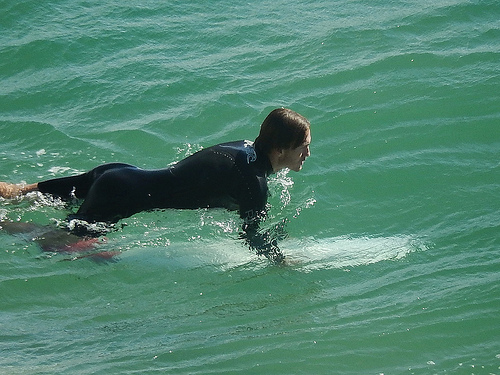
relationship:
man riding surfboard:
[0, 106, 312, 263] [117, 234, 412, 273]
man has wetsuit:
[0, 106, 312, 263] [38, 137, 272, 237]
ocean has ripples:
[2, 0, 498, 374] [1, 0, 499, 374]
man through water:
[0, 106, 312, 263] [3, 3, 500, 373]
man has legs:
[0, 106, 312, 263] [1, 183, 118, 267]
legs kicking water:
[1, 183, 118, 267] [3, 3, 500, 373]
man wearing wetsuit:
[0, 106, 312, 263] [38, 137, 272, 237]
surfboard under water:
[117, 234, 412, 273] [3, 3, 500, 373]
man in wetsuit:
[0, 106, 312, 263] [38, 137, 272, 237]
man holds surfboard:
[0, 106, 312, 263] [117, 234, 412, 273]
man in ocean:
[0, 106, 312, 263] [2, 0, 498, 374]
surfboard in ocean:
[117, 234, 412, 273] [2, 0, 498, 374]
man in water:
[0, 106, 312, 263] [3, 3, 500, 373]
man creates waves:
[0, 106, 312, 263] [1, 168, 305, 259]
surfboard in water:
[117, 234, 412, 273] [3, 3, 500, 373]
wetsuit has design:
[38, 137, 272, 237] [222, 137, 257, 166]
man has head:
[0, 106, 312, 263] [255, 109, 312, 174]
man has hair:
[0, 106, 312, 263] [257, 108, 311, 160]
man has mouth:
[0, 106, 312, 263] [298, 158, 305, 165]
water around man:
[3, 3, 500, 373] [0, 106, 312, 263]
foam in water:
[2, 145, 116, 234] [3, 3, 500, 373]